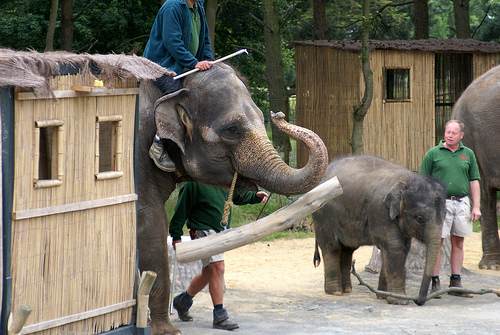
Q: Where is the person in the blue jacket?
A: Riding the elephant.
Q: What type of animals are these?
A: Elephants.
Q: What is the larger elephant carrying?
A: Log.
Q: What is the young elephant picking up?
A: Stick.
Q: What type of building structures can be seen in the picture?
A: Huts.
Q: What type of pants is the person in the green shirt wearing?
A: Shorts.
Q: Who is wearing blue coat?
A: Person on elephant.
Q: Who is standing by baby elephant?
A: Man in green shirt.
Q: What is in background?
A: Trees.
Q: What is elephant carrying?
A: A log.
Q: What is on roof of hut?
A: Straw.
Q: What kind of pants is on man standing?
A: Khaki shorts.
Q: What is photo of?
A: Elephants in city.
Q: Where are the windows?
A: On a shack.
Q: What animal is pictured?
A: Elephants.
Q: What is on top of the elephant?
A: A man.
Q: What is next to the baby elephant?
A: A man in green.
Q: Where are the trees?
A: Behind the buildings.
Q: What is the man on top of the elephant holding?
A: A stick.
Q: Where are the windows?
A: On the huts.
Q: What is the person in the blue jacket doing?
A: Riding an elephant.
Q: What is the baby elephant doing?
A: Trying to pick up a stick.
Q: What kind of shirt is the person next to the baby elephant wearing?
A: Collared shirt.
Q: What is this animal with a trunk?
A: Elephant.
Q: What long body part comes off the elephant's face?
A: Trunk.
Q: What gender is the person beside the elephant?
A: Male.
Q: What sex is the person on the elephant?
A: Male.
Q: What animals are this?
A: Elephants.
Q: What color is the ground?
A: Grey.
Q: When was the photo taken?
A: Daytime.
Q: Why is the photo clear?
A: Its during the day.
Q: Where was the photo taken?
A: At a zoo.